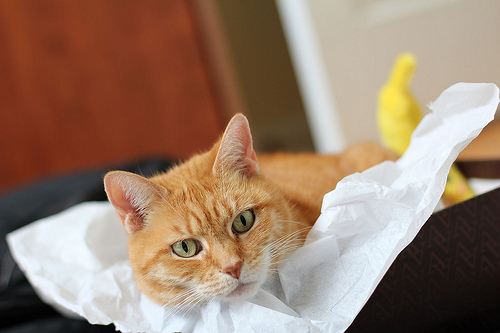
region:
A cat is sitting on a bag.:
[95, 75, 470, 305]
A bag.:
[335, 175, 496, 326]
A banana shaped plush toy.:
[370, 52, 485, 217]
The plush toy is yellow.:
[375, 50, 475, 210]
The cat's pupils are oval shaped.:
[150, 196, 260, 252]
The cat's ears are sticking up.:
[102, 105, 277, 305]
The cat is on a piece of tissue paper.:
[10, 75, 490, 327]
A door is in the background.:
[0, 0, 262, 167]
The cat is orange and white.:
[92, 95, 442, 295]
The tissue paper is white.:
[15, 71, 495, 329]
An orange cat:
[74, 96, 436, 313]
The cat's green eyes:
[151, 219, 278, 256]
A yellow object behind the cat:
[371, 51, 487, 204]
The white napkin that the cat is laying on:
[2, 217, 420, 327]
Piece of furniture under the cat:
[349, 186, 492, 326]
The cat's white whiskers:
[164, 213, 297, 328]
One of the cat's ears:
[86, 171, 178, 232]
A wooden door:
[7, 46, 273, 168]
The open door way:
[124, 7, 342, 138]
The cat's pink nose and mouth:
[206, 256, 271, 304]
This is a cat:
[83, 124, 384, 320]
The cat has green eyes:
[101, 141, 310, 283]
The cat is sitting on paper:
[76, 172, 472, 310]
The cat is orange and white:
[78, 124, 414, 315]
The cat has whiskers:
[55, 96, 346, 325]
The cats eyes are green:
[122, 155, 312, 279]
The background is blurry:
[47, 15, 433, 168]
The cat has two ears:
[82, 140, 357, 253]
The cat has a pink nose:
[193, 231, 303, 305]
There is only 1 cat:
[36, 13, 387, 295]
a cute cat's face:
[99, 110, 308, 306]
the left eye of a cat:
[228, 206, 258, 234]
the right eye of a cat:
[165, 237, 202, 257]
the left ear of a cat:
[203, 110, 261, 180]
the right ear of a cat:
[93, 162, 164, 229]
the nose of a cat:
[222, 259, 242, 277]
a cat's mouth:
[224, 278, 260, 298]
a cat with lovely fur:
[96, 132, 389, 299]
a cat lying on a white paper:
[11, 82, 498, 331]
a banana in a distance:
[380, 45, 479, 195]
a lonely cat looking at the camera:
[98, 110, 401, 300]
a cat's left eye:
[228, 202, 257, 231]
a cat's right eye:
[171, 234, 201, 257]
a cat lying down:
[108, 118, 412, 300]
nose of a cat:
[213, 248, 243, 275]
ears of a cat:
[82, 101, 279, 213]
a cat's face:
[91, 104, 293, 306]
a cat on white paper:
[23, 65, 497, 330]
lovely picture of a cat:
[1, 0, 495, 331]